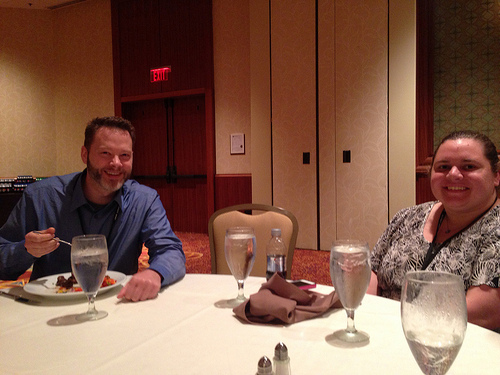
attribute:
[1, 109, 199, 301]
man — wearing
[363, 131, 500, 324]
woman — wearing, sitting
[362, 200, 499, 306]
shirt — black, white